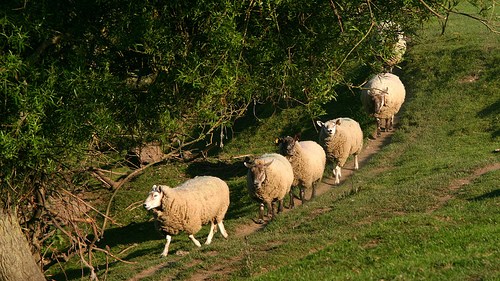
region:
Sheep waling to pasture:
[266, 144, 311, 198]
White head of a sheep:
[143, 191, 160, 208]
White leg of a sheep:
[163, 242, 165, 254]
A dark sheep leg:
[257, 208, 261, 220]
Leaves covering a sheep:
[380, 32, 394, 57]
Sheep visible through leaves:
[397, 40, 404, 54]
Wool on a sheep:
[166, 213, 187, 226]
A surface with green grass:
[404, 243, 448, 266]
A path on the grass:
[244, 224, 254, 231]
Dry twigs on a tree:
[55, 206, 77, 224]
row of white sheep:
[113, 11, 439, 272]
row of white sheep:
[71, 13, 469, 267]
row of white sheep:
[98, 23, 423, 258]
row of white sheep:
[95, 18, 425, 278]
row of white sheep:
[90, 21, 448, 276]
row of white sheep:
[91, 11, 438, 265]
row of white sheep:
[101, 12, 482, 273]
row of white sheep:
[122, 18, 446, 279]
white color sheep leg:
[156, 230, 171, 257]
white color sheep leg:
[186, 234, 202, 249]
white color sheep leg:
[203, 220, 216, 243]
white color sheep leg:
[215, 220, 231, 242]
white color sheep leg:
[333, 163, 342, 183]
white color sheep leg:
[348, 150, 358, 169]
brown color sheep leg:
[309, 184, 318, 201]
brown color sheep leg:
[277, 197, 284, 211]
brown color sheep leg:
[268, 200, 275, 218]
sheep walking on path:
[145, 18, 402, 240]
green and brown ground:
[380, 120, 476, 276]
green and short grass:
[333, 171, 444, 276]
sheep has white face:
[140, 176, 157, 213]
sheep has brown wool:
[145, 193, 250, 246]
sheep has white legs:
[157, 193, 233, 253]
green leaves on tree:
[0, 15, 327, 131]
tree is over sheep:
[1, 3, 351, 133]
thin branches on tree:
[5, 150, 220, 275]